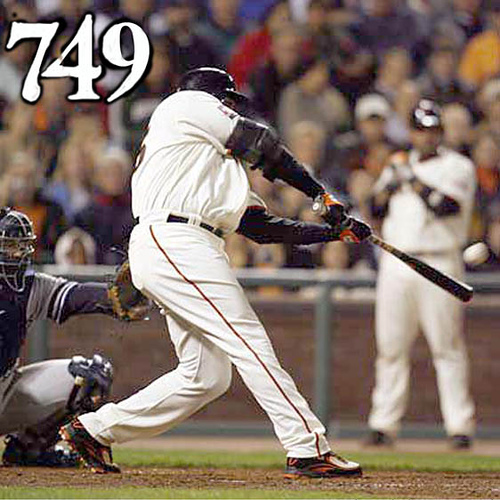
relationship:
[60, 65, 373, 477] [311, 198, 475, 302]
baseball player swinging a bat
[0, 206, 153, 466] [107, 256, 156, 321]
catcher holding mitt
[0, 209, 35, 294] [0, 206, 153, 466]
mask on catcher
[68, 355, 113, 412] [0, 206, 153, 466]
knee pad on catcher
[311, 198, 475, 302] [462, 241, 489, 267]
bat hitting baseball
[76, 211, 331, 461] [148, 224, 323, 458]
pants has a stripe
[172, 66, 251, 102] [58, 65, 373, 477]
helmet on baseball player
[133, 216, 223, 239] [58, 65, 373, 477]
belt on baseball player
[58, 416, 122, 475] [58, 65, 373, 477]
shoe on baseball player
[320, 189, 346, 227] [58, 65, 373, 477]
glove on baseball player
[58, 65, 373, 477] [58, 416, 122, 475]
baseball player wearing a shoe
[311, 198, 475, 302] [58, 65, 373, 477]
bat in front of baseball player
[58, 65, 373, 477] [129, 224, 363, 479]
baseball player has an extended leg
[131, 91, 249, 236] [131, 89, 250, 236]
shirt has wrinkles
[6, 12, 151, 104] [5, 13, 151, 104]
749 in white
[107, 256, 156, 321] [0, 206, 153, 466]
mitt on hand by catcher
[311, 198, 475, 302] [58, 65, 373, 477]
bat held by baseball player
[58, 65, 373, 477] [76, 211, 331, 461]
baseball player wearing pants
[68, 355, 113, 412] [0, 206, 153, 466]
knee pad worn by catcher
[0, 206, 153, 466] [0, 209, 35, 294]
catcher wearing a mask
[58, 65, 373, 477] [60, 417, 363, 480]
baseball player wearing shoes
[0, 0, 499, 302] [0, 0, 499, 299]
people in audience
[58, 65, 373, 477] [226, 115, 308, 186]
baseball player wearing an elbow pad